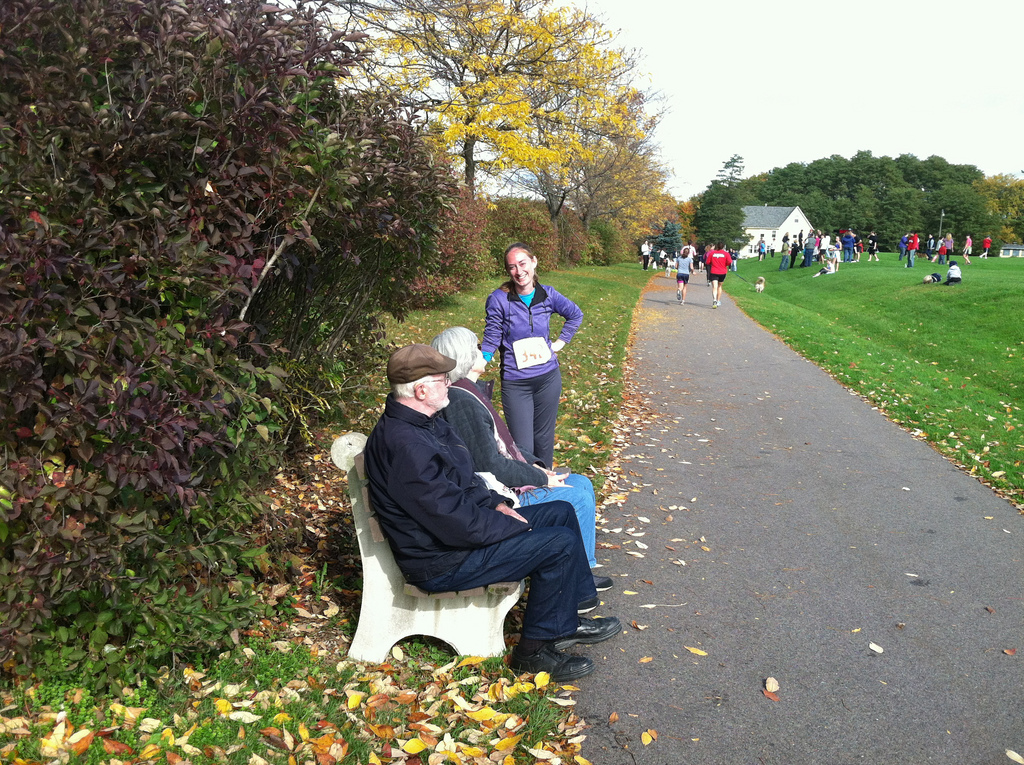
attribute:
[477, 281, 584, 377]
jacket — purple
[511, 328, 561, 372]
sticker — white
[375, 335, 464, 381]
hat — brown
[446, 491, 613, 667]
pants — dark blue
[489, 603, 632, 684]
boots — black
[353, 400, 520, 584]
jacket — dark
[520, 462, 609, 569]
pants — light blue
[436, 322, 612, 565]
woman — older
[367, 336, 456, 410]
hat — brown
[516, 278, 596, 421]
jacket — purple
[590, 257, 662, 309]
leaves — yellow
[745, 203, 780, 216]
roof —  gray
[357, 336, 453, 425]
hat — brown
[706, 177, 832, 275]
house — white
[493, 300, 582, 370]
jacket — purple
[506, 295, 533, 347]
jacket — purple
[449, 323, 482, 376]
hair — grey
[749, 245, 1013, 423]
grass — green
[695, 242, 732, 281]
shirt — red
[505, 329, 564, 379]
sign — white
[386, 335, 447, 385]
hat — brown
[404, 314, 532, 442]
lady — old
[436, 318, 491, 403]
hair — white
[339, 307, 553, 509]
couple — older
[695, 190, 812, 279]
building — white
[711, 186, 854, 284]
building — white